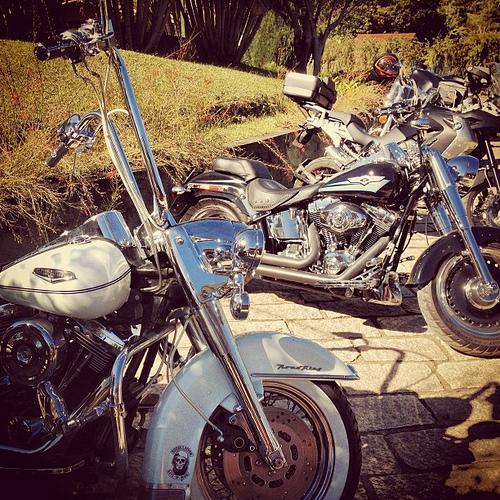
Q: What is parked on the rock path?
A: A motorcycle is parked.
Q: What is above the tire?
A: The front fender.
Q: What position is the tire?
A: Front of the white bike.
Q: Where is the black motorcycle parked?
A: On the pavement.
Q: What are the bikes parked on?
A: The bikes are parked on brick pavement.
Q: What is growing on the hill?
A: Green grass is growing.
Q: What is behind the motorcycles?
A: Green grass.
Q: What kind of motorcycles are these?
A: Harley.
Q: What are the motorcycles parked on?
A: Cobblestone.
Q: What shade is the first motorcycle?
A: Silver.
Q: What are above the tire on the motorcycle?
A: Headlight.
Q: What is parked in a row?
A: Motorcycles are parked.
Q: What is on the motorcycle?
A: A white gas tank.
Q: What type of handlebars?
A: Chrome handlebars.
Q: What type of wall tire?
A: White wall is on it.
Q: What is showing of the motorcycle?
A: A shadow is showing.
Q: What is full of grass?
A: The hill side.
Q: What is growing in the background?
A: Trees are growing.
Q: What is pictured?
A: Motorcycles.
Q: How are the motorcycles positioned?
A: Upright.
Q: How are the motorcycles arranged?
A: In a row.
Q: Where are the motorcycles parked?
A: On a stone surface.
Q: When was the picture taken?
A: During day hours.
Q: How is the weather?
A: Sunny.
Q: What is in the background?
A: Grass.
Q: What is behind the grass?
A: Trees.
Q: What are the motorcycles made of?
A: Metal.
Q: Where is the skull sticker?
A: On the wheel cover of the closest bike.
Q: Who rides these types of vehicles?
A: Biker.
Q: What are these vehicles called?
A: Motorcycles.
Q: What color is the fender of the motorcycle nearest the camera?
A: White.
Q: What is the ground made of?
A: Stones.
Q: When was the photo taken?
A: Daytime.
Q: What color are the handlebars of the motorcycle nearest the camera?
A: Silver.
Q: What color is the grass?
A: Green.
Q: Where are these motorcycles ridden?
A: Streets.